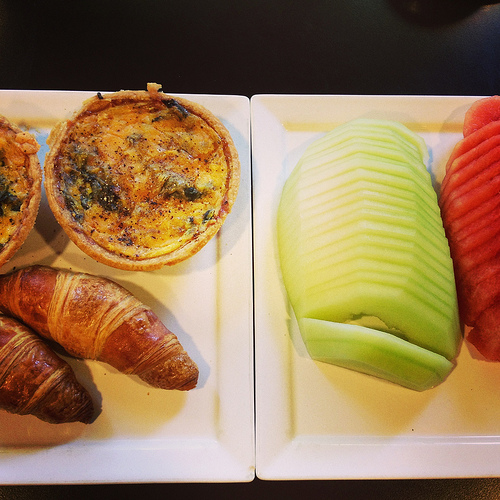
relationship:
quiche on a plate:
[46, 92, 239, 273] [1, 86, 256, 487]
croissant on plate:
[2, 263, 203, 391] [1, 86, 256, 487]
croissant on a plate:
[2, 263, 203, 391] [1, 86, 256, 487]